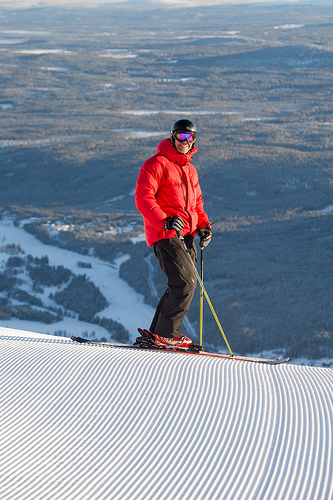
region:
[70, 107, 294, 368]
a skier on top of a ski slope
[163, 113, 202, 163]
the head of a man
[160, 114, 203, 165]
a man wearing a ski helmet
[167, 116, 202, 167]
a man wearing ski goggles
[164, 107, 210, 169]
a man who is smiling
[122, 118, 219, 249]
a man who is wearing a ski jacket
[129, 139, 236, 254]
a red ski jacket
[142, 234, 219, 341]
a pair of brown ski pants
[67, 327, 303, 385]
two snow skis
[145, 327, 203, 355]
a red and white ski boot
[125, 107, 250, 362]
This is a person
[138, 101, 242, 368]
this is a man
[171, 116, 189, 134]
this is a helmet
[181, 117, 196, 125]
the helmet is black in color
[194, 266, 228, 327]
this is a stick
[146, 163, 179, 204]
this is a jacket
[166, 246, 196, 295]
this is a trouser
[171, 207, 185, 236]
this is a glove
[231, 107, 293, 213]
this is a forest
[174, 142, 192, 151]
the man is light skinned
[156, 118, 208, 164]
the head of a man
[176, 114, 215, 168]
the face of a man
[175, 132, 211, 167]
the mouth of a man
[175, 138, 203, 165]
the chin of a man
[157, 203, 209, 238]
the hand of a man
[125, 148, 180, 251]
the arm of a man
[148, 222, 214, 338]
the leg of a man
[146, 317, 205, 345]
the foot of a man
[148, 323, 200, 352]
man wearing red snow boots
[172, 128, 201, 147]
man wearing snow googles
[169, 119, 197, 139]
man wearing a black helmet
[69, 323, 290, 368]
man on skis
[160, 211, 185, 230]
man wearing black gloves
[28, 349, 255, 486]
trails on the ground of the snow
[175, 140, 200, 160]
man with a smile on his face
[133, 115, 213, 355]
snowboarder man wearing red outfit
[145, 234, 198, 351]
dark pants of snowboarder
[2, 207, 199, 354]
large river in the background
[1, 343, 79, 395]
grooved ridge in the ski slope